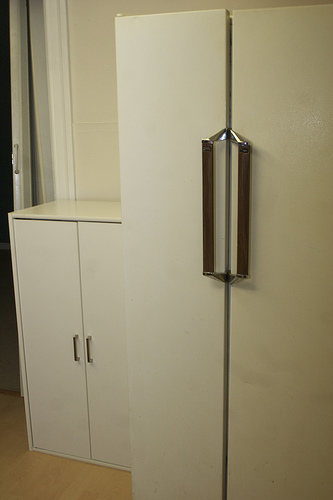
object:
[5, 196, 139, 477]
cabinet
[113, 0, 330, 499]
refrigerator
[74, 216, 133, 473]
door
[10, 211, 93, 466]
door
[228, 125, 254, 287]
handle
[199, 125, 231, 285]
handle